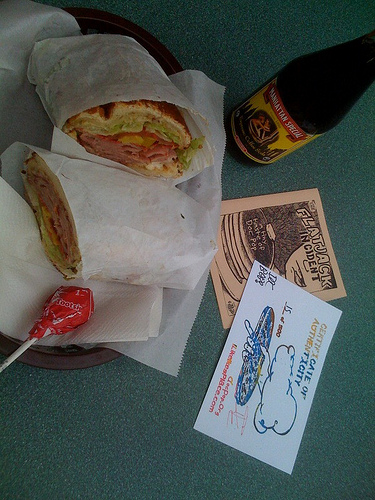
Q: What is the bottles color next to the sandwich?
A: Dark brown.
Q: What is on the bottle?
A: A yellow, brown and red label.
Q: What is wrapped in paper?
A: Half a sandwich wrapped in white paper.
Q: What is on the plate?
A: Half a sandwich wrapped in white paper.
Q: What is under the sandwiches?
A: A white paper under sandwiches.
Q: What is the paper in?
A: A brown serving basket.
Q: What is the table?
A: The table is green.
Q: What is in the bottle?
A: Manhattan Special espresso coffee soda.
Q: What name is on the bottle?
A: Manhattan Special.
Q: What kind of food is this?
A: A sandwich.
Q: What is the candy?
A: The candy is a lollipop.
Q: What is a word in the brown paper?
A: FLATJACK.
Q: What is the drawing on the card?
A: A cloud with a hand.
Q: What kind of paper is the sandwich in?
A: Wax paper.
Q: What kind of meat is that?
A: Ham.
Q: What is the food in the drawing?
A: A stack of pancakes.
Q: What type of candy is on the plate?
A: A tootsie pop.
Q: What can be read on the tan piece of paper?
A: Flatjack Incident.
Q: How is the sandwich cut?
A: In half.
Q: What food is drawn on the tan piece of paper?
A: Pancakes.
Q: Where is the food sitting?
A: On a table.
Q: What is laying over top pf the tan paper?
A: A white card.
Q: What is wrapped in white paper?
A: The sandwich.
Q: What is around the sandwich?
A: A paper.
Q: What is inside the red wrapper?
A: A sucker.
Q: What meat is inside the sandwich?
A: Ham.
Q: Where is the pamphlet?
A: Over green table.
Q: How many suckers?
A: One.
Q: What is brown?
A: Paper.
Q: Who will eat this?
A: Man.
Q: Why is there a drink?
A: To go with the sandwich.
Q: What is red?
A: Sucker.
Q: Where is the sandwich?
A: In the basket.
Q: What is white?
A: Paper.